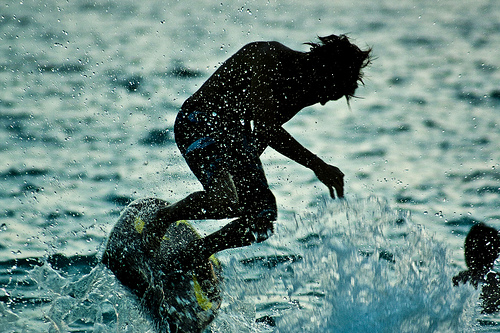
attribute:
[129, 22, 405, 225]
person — on vacation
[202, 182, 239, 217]
knee — bent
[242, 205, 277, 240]
knee — bent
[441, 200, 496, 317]
person — in silhouette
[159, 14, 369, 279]
person — enjoying their day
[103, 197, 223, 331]
surfboard — yellow , black , splashing water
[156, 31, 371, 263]
person — surfing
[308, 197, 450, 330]
water — splashing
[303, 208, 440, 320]
water — splashing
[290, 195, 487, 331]
splash — large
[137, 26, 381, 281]
person — getting some exercise, doing water sport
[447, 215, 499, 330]
person — getting some exercise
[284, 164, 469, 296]
water — going everywhere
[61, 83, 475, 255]
waves — going everywhere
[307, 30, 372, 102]
hair — wild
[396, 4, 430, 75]
water — blue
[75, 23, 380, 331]
wet person — very wet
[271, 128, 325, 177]
arm — extended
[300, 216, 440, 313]
water — splashing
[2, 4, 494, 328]
water — agitated, splashing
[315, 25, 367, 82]
hair — wet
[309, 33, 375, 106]
hair — sticking up